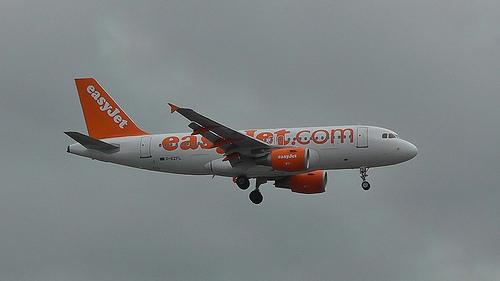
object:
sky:
[0, 2, 497, 279]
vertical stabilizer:
[73, 75, 153, 137]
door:
[138, 134, 154, 159]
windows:
[157, 134, 352, 147]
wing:
[172, 107, 270, 161]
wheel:
[246, 188, 264, 206]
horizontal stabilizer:
[62, 131, 114, 150]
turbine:
[270, 147, 312, 172]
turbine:
[289, 170, 328, 193]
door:
[353, 127, 370, 149]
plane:
[59, 76, 420, 205]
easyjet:
[82, 82, 129, 130]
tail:
[71, 77, 148, 137]